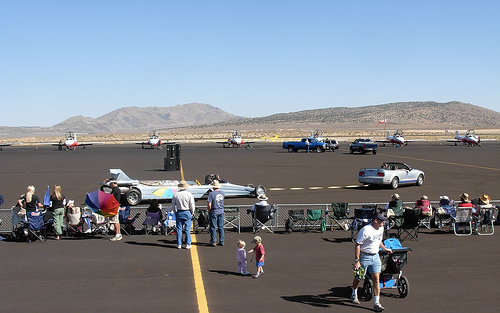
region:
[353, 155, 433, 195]
a sports car on an airport tarmac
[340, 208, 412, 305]
a man pulling a stroller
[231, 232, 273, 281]
two small children playing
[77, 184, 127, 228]
an umbrella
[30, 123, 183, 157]
airplanes on an airport tarmac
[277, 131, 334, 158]
a blue pickup truck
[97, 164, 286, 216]
a fast race car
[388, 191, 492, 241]
people sitting on lawn chairs on an airport tarmac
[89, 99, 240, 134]
a mountain in the background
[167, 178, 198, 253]
a man wearing a white hat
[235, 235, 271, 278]
two children playing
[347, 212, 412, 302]
man pulling a stroller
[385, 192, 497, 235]
people sitting in chairs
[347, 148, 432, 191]
silver convertible on road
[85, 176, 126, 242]
man with colorful umbrella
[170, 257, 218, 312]
yellow line on the road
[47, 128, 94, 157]
white and red plane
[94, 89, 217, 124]
mountains in the background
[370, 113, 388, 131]
red and white flag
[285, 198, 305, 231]
black lawn chair in front of the gate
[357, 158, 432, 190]
Silver mustang gt on an airport track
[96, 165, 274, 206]
Jet race car on a paved track for racing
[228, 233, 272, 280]
Two children playing at a top speed track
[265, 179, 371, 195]
Towing line behind a ford mustang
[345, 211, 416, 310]
Man pulling a baby stroller at a racing track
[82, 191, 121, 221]
Multi colored open umbrella being held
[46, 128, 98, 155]
Red and white airplane at a speed track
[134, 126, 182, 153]
Red and white airplane at a speed track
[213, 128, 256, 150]
Red and white airplane at a speed track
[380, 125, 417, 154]
Red and white airplane at a speed track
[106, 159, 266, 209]
race car on the track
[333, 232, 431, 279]
man pushing a stroller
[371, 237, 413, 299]
blue stroller with black wheels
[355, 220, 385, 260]
guy wearing white shirt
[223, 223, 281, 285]
two kids standing together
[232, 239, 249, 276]
child with blond hair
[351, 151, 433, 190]
silver Mercedes Benz on track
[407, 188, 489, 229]
people sitting in lounge chairs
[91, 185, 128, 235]
man holding umbrella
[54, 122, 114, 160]
Plane on the tarmac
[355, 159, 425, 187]
silver convertible car with the top down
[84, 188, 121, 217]
multi-colored large umbrella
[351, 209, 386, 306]
man in blue shorts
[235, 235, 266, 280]
two children playing together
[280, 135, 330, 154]
large blue pick up truck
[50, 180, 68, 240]
woman with long blonde hair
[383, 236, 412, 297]
black and blue stroller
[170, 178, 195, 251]
man wearing long sleeve tshirt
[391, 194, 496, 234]
people sitting in folding chairs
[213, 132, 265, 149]
red and white airplane